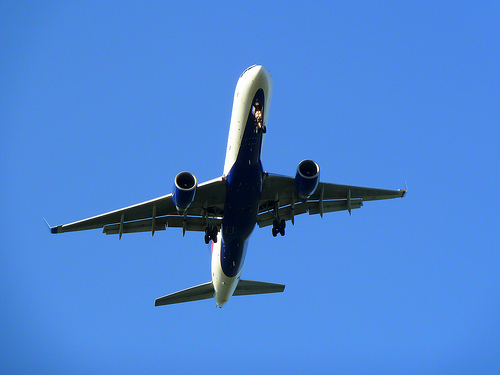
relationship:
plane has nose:
[42, 63, 406, 307] [245, 63, 269, 77]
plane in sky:
[42, 63, 406, 307] [2, 2, 500, 372]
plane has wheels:
[42, 63, 406, 307] [272, 219, 288, 238]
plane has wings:
[42, 63, 406, 307] [44, 159, 406, 245]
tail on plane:
[157, 279, 288, 308] [42, 63, 406, 307]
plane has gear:
[42, 63, 406, 307] [202, 207, 222, 227]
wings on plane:
[44, 159, 406, 245] [42, 63, 406, 307]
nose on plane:
[245, 63, 269, 77] [42, 63, 406, 307]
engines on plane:
[172, 172, 198, 218] [42, 63, 406, 307]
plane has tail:
[42, 63, 406, 307] [157, 279, 288, 308]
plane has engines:
[42, 63, 406, 307] [172, 172, 198, 218]